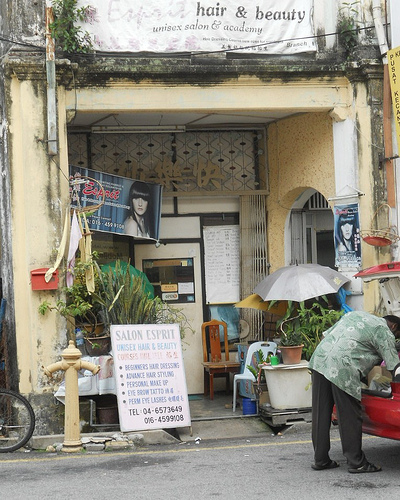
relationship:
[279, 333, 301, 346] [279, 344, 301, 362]
red plant in pot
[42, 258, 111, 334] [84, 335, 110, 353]
red plant in pot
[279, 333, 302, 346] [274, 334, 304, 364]
red plant in pot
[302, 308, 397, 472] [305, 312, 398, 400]
man on green shirt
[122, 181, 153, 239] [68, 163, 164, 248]
girl on banner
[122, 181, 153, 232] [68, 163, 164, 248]
girl on banner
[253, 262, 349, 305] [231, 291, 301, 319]
umbrellas near umbrella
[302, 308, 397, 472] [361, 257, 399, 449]
man bending over car trunk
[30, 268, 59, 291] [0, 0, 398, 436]
receptacle on building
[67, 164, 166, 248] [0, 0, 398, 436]
banner hanging in front of building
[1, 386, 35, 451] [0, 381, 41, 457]
tire on bike